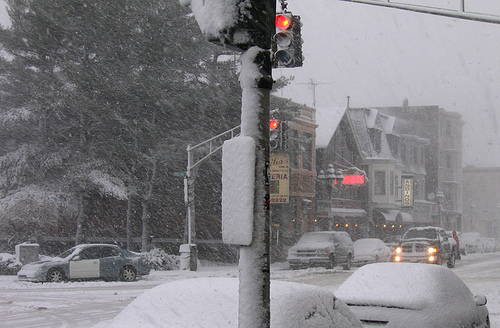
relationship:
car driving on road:
[17, 226, 499, 328] [0, 250, 499, 326]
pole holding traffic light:
[235, 2, 274, 327] [268, 9, 302, 69]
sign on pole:
[169, 167, 184, 177] [181, 142, 197, 269]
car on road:
[91, 273, 361, 326] [12, 242, 497, 326]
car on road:
[17, 226, 499, 328] [12, 242, 497, 326]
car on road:
[17, 226, 499, 328] [0, 250, 499, 326]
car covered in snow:
[17, 226, 499, 328] [94, 257, 496, 326]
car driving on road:
[17, 226, 499, 328] [12, 242, 497, 326]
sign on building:
[263, 144, 318, 235] [221, 93, 388, 280]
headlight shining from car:
[393, 241, 404, 260] [17, 226, 499, 328]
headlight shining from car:
[424, 247, 435, 262] [17, 226, 499, 328]